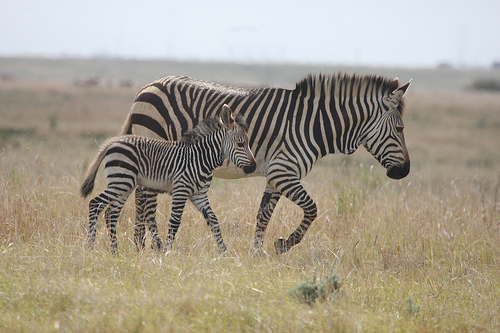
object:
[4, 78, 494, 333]
grass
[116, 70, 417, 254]
zebra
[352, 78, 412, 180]
head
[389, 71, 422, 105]
ear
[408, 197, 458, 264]
grass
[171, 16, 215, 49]
sky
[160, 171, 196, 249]
leg